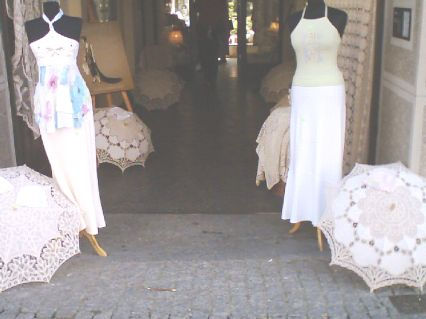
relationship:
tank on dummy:
[30, 10, 92, 130] [24, 2, 108, 255]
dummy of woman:
[24, 2, 108, 255] [80, 34, 103, 83]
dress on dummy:
[278, 4, 346, 227] [279, 0, 347, 236]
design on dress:
[44, 70, 59, 93] [20, 9, 102, 139]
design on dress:
[68, 83, 88, 116] [20, 9, 102, 139]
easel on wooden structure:
[72, 19, 135, 122] [87, 89, 135, 114]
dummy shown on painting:
[24, 2, 108, 255] [76, 15, 134, 94]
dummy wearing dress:
[279, 0, 347, 236] [278, 4, 346, 227]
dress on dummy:
[31, 13, 109, 236] [24, 2, 108, 255]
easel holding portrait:
[72, 19, 135, 122] [76, 17, 136, 94]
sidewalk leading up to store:
[0, 59, 426, 319] [2, 3, 381, 211]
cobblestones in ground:
[12, 259, 384, 315] [10, 130, 384, 316]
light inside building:
[267, 19, 283, 32] [76, 7, 346, 265]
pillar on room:
[233, 0, 247, 92] [2, 0, 308, 212]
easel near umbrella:
[72, 19, 135, 122] [92, 104, 157, 172]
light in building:
[170, 23, 185, 49] [135, 12, 345, 180]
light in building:
[267, 14, 285, 32] [135, 12, 345, 180]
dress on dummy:
[278, 4, 346, 227] [285, 0, 347, 34]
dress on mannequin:
[278, 4, 346, 227] [276, 4, 352, 241]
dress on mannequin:
[278, 4, 346, 227] [280, 0, 353, 45]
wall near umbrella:
[307, 0, 370, 213] [319, 161, 426, 293]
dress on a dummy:
[31, 26, 114, 260] [24, 4, 108, 255]